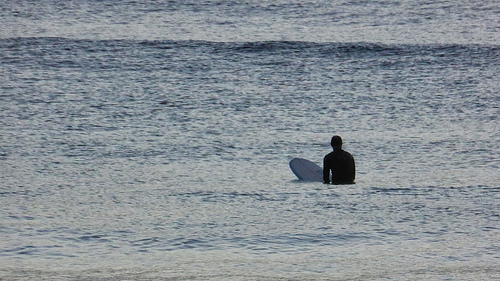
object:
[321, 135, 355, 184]
man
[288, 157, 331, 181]
board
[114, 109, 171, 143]
ocean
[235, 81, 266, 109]
water